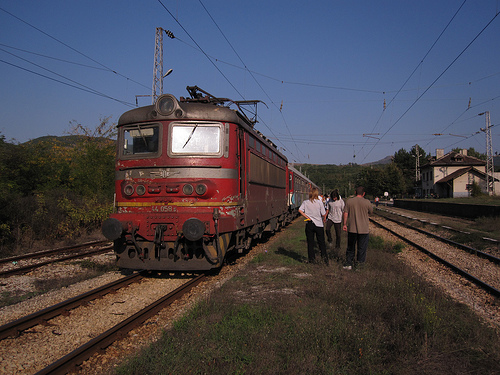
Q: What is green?
A: Grass.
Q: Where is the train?
A: On train tracks.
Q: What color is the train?
A: Red.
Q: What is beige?
A: A house.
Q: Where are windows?
A: On the train.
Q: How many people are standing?
A: Three.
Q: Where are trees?
A: In the distance.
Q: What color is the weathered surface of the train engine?
A: It is red.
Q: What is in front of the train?
A: Tracks and gravel.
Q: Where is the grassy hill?
A: On the side of the train.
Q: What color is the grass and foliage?
A: The grass and foliage is green.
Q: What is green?
A: The grass and foliage.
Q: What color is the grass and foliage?
A: The grass and foliage is green.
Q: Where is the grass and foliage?
A: On the side of the train.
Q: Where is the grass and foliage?
A: On the left side of the train.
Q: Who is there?
A: Passerbys.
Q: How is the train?
A: Old.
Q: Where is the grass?
A: Middle.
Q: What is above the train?
A: Wires.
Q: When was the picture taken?
A: Early evening.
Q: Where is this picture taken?
A: The train tracks.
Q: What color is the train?
A: Red.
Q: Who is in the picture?
A: Three people.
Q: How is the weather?
A: Clear.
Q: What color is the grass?
A: Green.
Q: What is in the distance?
A: A house.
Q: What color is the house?
A: White.